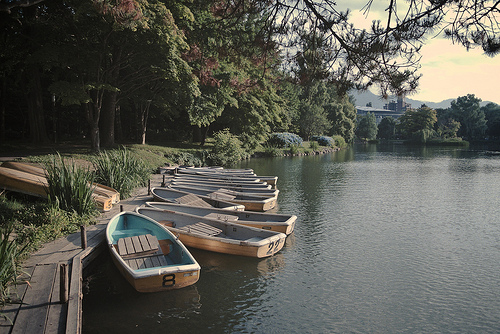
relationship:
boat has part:
[107, 206, 202, 293] [162, 271, 180, 288]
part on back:
[162, 271, 180, 288] [136, 267, 201, 294]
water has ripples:
[82, 150, 499, 333] [161, 270, 293, 333]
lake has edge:
[82, 150, 499, 333] [64, 236, 108, 334]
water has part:
[82, 150, 499, 333] [343, 169, 466, 252]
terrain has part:
[0, 125, 232, 286] [0, 149, 87, 203]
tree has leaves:
[1, 4, 194, 153] [105, 5, 184, 84]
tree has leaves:
[1, 4, 194, 153] [75, 3, 123, 84]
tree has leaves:
[1, 4, 194, 153] [29, 2, 80, 77]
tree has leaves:
[1, 4, 194, 153] [1, 8, 38, 90]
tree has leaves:
[1, 4, 194, 153] [117, 9, 198, 107]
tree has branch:
[1, 4, 194, 153] [110, 34, 125, 82]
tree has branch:
[1, 4, 194, 153] [73, 45, 94, 88]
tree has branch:
[1, 4, 194, 153] [120, 60, 149, 86]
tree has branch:
[1, 4, 194, 153] [14, 36, 51, 94]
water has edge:
[82, 150, 499, 333] [64, 236, 108, 334]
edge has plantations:
[64, 236, 108, 334] [1, 214, 30, 293]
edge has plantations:
[64, 236, 108, 334] [41, 149, 92, 230]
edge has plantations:
[64, 236, 108, 334] [16, 198, 66, 250]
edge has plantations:
[64, 236, 108, 334] [85, 155, 129, 198]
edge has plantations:
[64, 236, 108, 334] [111, 149, 150, 185]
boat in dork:
[107, 206, 202, 293] [0, 151, 185, 332]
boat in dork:
[133, 206, 286, 258] [0, 151, 185, 332]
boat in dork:
[153, 185, 244, 213] [0, 151, 185, 332]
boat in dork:
[173, 183, 279, 212] [0, 151, 185, 332]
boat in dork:
[169, 175, 272, 190] [0, 151, 185, 332]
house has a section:
[354, 104, 405, 120] [370, 108, 377, 110]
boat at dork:
[107, 206, 202, 293] [0, 151, 185, 332]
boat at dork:
[133, 206, 286, 258] [0, 151, 185, 332]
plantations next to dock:
[111, 149, 150, 185] [0, 150, 179, 329]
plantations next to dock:
[85, 155, 129, 198] [0, 150, 179, 329]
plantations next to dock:
[41, 149, 92, 230] [0, 150, 179, 329]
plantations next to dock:
[16, 198, 66, 250] [0, 150, 179, 329]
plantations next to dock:
[1, 214, 30, 293] [0, 150, 179, 329]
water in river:
[82, 150, 499, 333] [74, 137, 491, 334]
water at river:
[82, 150, 499, 333] [74, 137, 491, 334]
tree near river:
[1, 4, 194, 153] [74, 137, 491, 334]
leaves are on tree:
[117, 9, 198, 107] [1, 4, 194, 153]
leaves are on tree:
[105, 5, 184, 84] [1, 4, 194, 153]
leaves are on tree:
[75, 3, 123, 84] [1, 4, 194, 153]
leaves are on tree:
[29, 2, 80, 77] [1, 4, 194, 153]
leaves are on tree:
[1, 8, 38, 90] [1, 4, 194, 153]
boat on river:
[107, 206, 202, 293] [74, 137, 491, 334]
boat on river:
[133, 206, 286, 258] [74, 137, 491, 334]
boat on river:
[153, 185, 244, 213] [74, 137, 491, 334]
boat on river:
[173, 183, 279, 212] [74, 137, 491, 334]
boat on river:
[169, 175, 272, 190] [74, 137, 491, 334]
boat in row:
[107, 206, 202, 293] [105, 163, 297, 295]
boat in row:
[173, 183, 279, 212] [105, 163, 297, 295]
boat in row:
[153, 185, 244, 213] [105, 163, 297, 295]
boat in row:
[133, 206, 286, 258] [105, 163, 297, 295]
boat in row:
[169, 175, 272, 190] [105, 163, 297, 295]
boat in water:
[107, 206, 202, 293] [82, 150, 499, 333]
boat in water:
[133, 206, 286, 258] [82, 150, 499, 333]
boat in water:
[153, 185, 244, 213] [82, 150, 499, 333]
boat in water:
[173, 183, 279, 212] [82, 150, 499, 333]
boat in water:
[169, 175, 272, 190] [82, 150, 499, 333]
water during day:
[82, 150, 499, 333] [0, 3, 499, 332]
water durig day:
[82, 150, 499, 333] [0, 3, 499, 332]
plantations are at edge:
[111, 149, 150, 185] [4, 157, 181, 334]